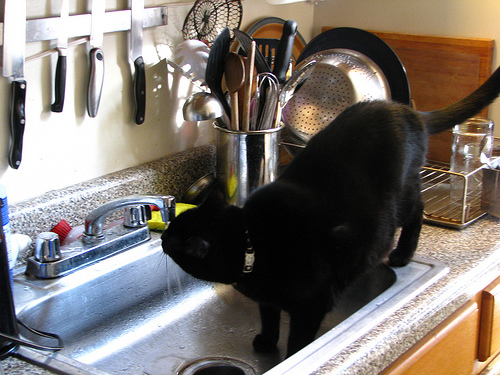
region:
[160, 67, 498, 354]
black cat standing in sink and drinking from faucet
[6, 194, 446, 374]
silver sink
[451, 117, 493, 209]
glass upside down in rack behind cat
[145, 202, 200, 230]
yellow sponge in the back corner of the sink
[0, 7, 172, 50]
magnetic bar on the wall that holds knives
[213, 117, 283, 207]
silver can that holds many items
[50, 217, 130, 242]
brush with red bristles behind faucet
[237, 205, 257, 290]
black collar with white clasp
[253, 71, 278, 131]
wire whisk in silver can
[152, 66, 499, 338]
a black cat in a sink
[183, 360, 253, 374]
drain in a sink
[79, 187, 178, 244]
arm of a faucet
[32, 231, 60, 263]
knob for a sink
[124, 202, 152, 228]
knob for a sink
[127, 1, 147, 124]
a knife on a magnetic rack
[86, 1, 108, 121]
a knife on a magnetic rack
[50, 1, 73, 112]
a knife on a magnetic rack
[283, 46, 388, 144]
a metal collander in a bowl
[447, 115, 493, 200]
a glass in a rack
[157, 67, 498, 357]
black cat inside kitchen sink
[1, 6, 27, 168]
knife hanging behind kitchen sink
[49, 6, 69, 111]
knife hanging behind kitchen sink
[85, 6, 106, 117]
knife hanging behind kitchen sink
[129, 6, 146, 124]
knife hanging behind kitchen sink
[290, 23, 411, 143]
black pan on dish rack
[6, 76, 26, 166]
knife with black handle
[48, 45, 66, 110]
knife with black handle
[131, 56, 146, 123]
knife with black handle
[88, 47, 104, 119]
knife with silver handle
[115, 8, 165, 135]
A big knife on the holder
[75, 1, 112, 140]
A big knife on the holder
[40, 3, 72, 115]
A big knife on the holder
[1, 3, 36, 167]
A big knife on the holder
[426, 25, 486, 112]
A wooden chopping board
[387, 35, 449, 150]
A wooden chopping board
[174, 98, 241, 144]
A silver serving spoon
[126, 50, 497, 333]
this is a cat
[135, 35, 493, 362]
the cat is black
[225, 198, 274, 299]
cat wearing a collar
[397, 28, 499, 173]
cat tail sticking out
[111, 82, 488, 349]
a cat in a sink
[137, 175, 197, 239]
yellow sponge on sink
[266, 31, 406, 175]
silver strainer next to sink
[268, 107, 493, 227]
silver dish dryer on counter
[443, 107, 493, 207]
clear glass in dish dryer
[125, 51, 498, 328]
A black cat drinking water from the sink faucet.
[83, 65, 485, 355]
Cat in the sink trying to drink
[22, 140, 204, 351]
Water coming out of the faucet for the black feline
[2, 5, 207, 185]
Knives on the wall on the magnetic holder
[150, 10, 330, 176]
Utensils in the utensil holder next to the sink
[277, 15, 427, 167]
Metal colander in the dish basket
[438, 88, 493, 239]
Clean glass in the dish basket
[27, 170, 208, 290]
Metal faucet on the sink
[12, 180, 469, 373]
Single large sink in the kitchen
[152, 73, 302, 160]
Metal ladle in the utensil holder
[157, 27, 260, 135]
Plastic spaghetti server in the utensil holder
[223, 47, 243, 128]
kitchen utensil by the sink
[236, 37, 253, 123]
kitchen utensil by the sink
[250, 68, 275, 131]
kitchen utensil by the sink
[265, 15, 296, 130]
kitchen utensil by the sink